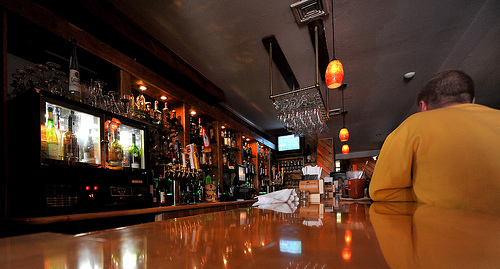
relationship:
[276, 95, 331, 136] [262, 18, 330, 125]
glasses on rack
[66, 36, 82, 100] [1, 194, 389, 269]
bottle behind bar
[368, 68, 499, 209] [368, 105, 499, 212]
man wears shirt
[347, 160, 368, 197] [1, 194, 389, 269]
drink on bar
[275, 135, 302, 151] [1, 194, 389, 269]
tv near bar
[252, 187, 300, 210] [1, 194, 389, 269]
towel on bar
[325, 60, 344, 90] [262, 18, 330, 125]
light near rack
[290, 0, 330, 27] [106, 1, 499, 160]
vent on ceiling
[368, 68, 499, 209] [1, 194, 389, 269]
man sits at bar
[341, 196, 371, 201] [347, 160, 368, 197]
napkin under drink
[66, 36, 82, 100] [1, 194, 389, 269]
bottle at bar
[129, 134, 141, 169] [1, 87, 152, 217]
bottle in refrigerator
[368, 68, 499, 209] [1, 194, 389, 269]
man at bar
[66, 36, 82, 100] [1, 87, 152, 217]
bottle on refrigerator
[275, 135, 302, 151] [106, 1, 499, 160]
tv near ceiling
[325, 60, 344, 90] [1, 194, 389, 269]
light over bar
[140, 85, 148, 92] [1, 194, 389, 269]
light behind bar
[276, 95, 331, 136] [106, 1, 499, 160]
glasses near ceiling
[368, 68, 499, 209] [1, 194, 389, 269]
man leans on bar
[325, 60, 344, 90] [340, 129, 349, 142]
light near light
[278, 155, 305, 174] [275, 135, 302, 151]
shelf under tv